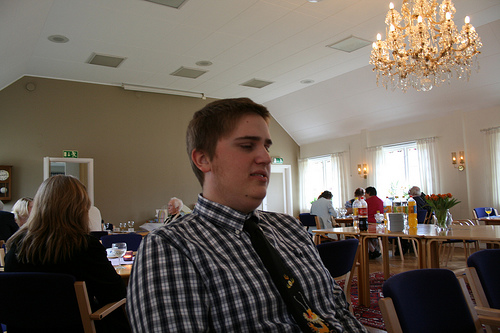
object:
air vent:
[169, 65, 206, 79]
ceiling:
[0, 2, 500, 95]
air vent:
[84, 50, 126, 68]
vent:
[87, 52, 123, 69]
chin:
[237, 183, 268, 203]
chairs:
[382, 269, 482, 332]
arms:
[379, 299, 404, 332]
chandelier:
[369, 1, 489, 93]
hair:
[184, 97, 273, 186]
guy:
[126, 98, 359, 332]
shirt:
[365, 196, 384, 222]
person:
[365, 186, 384, 223]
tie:
[243, 218, 343, 330]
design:
[302, 310, 327, 326]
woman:
[8, 173, 88, 298]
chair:
[72, 283, 95, 333]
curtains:
[367, 137, 441, 199]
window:
[366, 142, 432, 204]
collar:
[194, 195, 262, 233]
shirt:
[124, 193, 364, 333]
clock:
[0, 165, 13, 202]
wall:
[0, 75, 298, 231]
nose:
[254, 149, 272, 164]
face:
[212, 114, 272, 201]